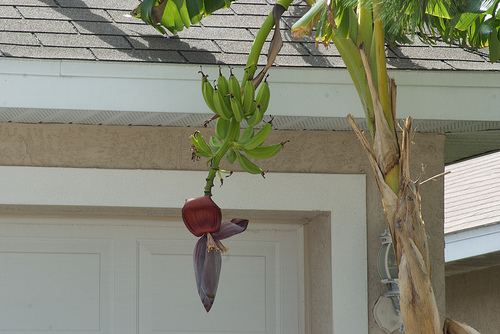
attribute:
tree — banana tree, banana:
[133, 0, 499, 334]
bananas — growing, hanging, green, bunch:
[184, 64, 292, 187]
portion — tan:
[1, 120, 375, 179]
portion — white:
[0, 71, 499, 123]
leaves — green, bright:
[128, 0, 499, 69]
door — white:
[0, 196, 341, 333]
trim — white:
[1, 170, 370, 333]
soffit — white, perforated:
[10, 105, 500, 171]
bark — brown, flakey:
[348, 36, 444, 333]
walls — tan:
[1, 120, 448, 333]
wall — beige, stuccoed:
[1, 120, 450, 334]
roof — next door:
[437, 125, 500, 167]